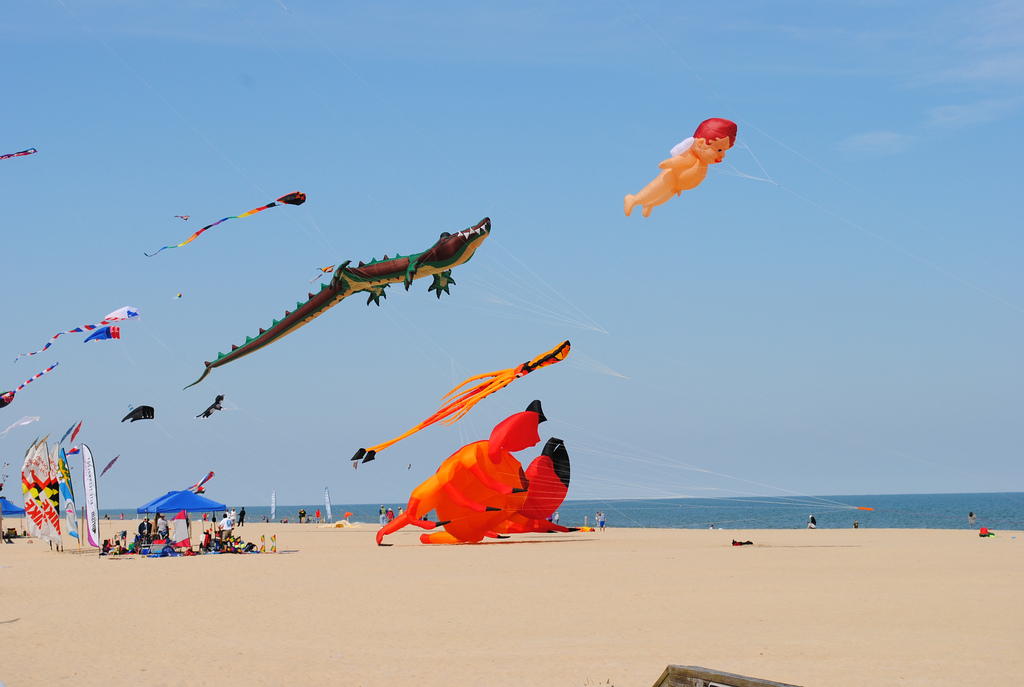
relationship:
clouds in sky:
[819, 77, 1006, 169] [0, 5, 1024, 505]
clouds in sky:
[572, 315, 646, 398] [0, 5, 1024, 505]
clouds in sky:
[723, 8, 1021, 161] [0, 5, 1024, 505]